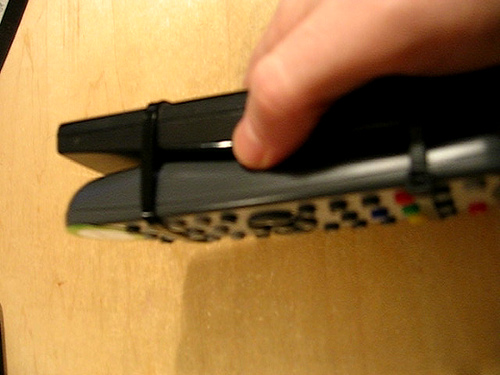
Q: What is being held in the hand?
A: Remotes.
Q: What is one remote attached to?
A: Another remote.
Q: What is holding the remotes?
A: Hand.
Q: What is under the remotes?
A: Table.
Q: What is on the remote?
A: Buttons.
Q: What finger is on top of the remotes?
A: Thumb.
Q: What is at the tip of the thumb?
A: Nail.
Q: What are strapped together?
A: Two remotes.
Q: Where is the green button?
A: Between the red and yellow buttons.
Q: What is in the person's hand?
A: Two remotes.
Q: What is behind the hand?
A: Wood.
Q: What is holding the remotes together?
A: Zip ties.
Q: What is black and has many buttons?
A: The remotes.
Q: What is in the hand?
A: Remotes.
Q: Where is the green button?
A: Between the red and yellow buttons.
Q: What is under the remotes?
A: Table.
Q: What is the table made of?
A: Wood.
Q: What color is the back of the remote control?
A: Black.